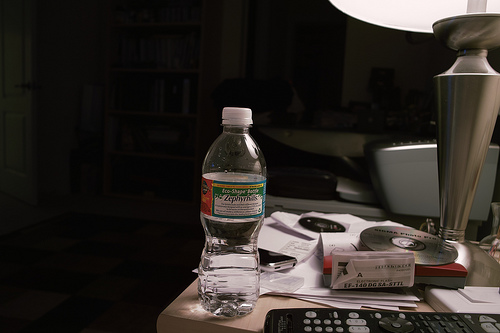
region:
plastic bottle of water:
[198, 105, 264, 316]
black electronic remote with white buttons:
[263, 304, 499, 331]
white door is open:
[0, 1, 43, 207]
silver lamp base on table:
[411, 12, 498, 299]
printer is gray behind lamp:
[363, 130, 499, 225]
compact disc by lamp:
[361, 220, 458, 269]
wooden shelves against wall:
[102, 3, 218, 216]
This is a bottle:
[190, 94, 281, 331]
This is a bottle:
[190, 96, 274, 322]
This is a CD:
[354, 212, 463, 274]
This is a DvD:
[355, 217, 460, 276]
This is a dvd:
[297, 210, 348, 240]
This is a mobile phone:
[252, 235, 302, 279]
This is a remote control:
[261, 297, 498, 332]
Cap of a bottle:
[217, 102, 260, 139]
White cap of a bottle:
[204, 99, 266, 136]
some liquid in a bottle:
[185, 92, 277, 332]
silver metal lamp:
[322, 0, 499, 284]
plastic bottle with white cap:
[195, 102, 270, 317]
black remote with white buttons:
[262, 305, 498, 332]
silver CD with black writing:
[361, 222, 459, 266]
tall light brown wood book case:
[95, 4, 223, 208]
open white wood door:
[0, 0, 43, 208]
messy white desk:
[156, 203, 498, 331]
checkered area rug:
[2, 208, 202, 331]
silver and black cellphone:
[257, 245, 296, 274]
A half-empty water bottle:
[192, 99, 269, 319]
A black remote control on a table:
[258, 304, 499, 331]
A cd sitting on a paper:
[356, 222, 461, 268]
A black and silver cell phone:
[256, 243, 297, 273]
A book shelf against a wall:
[101, 74, 211, 223]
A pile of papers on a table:
[274, 210, 369, 263]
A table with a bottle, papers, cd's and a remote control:
[151, 106, 497, 331]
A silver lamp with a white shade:
[336, 0, 499, 245]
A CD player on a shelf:
[213, 74, 298, 126]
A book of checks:
[324, 249, 417, 294]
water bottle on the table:
[183, 95, 278, 317]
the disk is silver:
[353, 222, 454, 286]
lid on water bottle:
[213, 100, 263, 123]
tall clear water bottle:
[186, 98, 278, 332]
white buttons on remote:
[291, 310, 333, 328]